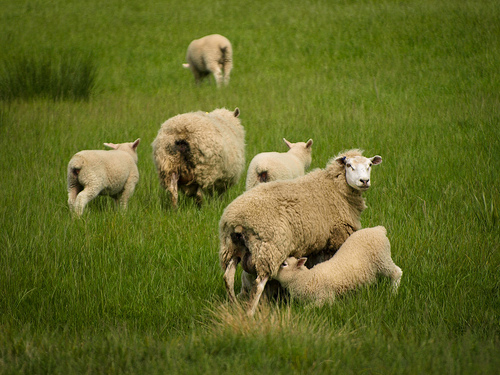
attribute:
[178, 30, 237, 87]
sheep — grazing , Tan 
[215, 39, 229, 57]
tail — tiny 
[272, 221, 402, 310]
lamb — nursing 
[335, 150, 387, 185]
head — White 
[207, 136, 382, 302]
sheep — mommy 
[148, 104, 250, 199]
sheep — Largest , walking away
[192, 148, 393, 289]
sheep — nursing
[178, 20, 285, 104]
sheep — away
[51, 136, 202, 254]
sheep — following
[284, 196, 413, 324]
sheep — nursing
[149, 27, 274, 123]
sheep — eating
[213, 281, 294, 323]
grass — patchy, yellowed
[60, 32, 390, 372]
sheep — walking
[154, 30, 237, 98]
sheep — grazing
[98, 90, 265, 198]
sheep — mother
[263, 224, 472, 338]
sheep — baby, sucking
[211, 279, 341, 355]
grass — yellow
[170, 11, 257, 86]
sheep — eating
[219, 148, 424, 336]
sheep — baby, grown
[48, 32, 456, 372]
sheeps — standing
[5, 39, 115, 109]
grass — tall, green